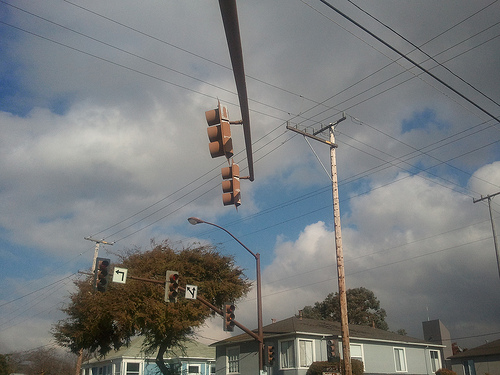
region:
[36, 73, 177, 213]
It is a cloudy day with blue skies.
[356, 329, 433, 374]
A grey house is next to the intersection.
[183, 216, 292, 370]
A street light is combined with traffic lights.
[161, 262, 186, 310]
Traffic light is red.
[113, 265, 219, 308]
There are two signs on the traffic light.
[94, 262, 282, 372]
There are 4 traffic lights on one pole.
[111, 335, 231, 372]
A blue house is next door to a grey house.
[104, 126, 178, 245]
Power lines are above the intersection.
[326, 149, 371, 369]
There is one wooden post near intersection.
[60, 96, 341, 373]
traffic lights at an intersection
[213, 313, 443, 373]
a house with blue siding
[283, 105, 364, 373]
a wooden power pole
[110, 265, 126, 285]
right-turn lane sign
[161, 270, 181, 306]
red traffic light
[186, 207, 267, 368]
a street light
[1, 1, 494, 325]
the sky is cloudy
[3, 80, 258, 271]
a cloud in the sky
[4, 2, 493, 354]
clouds are white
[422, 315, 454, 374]
a tall building in the distance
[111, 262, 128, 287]
Arrow on the sign.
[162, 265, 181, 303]
Traffic light on the pole.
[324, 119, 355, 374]
Telephone pole in the forefront.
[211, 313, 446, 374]
Gray house in the forefront.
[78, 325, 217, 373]
Blue house in the back.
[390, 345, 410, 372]
Window in the house.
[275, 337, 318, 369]
Corner window on the house.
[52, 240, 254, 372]
Tree in front of the house.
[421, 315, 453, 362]
Gray building in the background.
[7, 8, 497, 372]
White clouds in the sky.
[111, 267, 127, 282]
white sign with a black arrow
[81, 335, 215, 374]
light blue house with white trim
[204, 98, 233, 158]
rusted metal street light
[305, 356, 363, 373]
green bush in front of the house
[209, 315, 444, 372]
gray house with white trim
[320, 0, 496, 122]
thick black power line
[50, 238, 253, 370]
large tree with a crooked trunk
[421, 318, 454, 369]
large gray concrete pillar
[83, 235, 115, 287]
part of a power pole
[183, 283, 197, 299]
white sign with two black arrows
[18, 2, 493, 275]
Black wires crossing over the road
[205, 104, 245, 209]
Street signal is brown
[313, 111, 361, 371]
Telephone tower is brown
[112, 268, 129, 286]
White and black sign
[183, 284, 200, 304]
Sign with black arrows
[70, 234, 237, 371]
Tall tree behind the light signal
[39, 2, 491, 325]
Large clouds in the sky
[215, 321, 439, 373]
Blue house with a black roof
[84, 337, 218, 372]
Light blue house with white windows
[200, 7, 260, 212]
Light signals attached to a grey pole